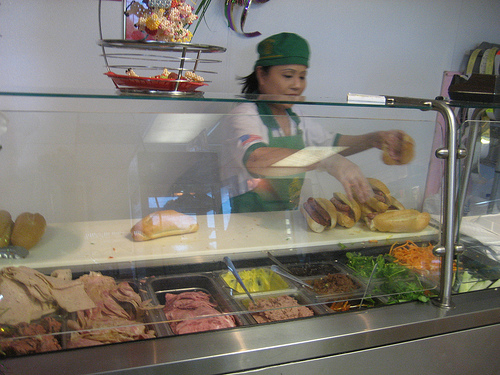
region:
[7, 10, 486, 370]
photograph taken in a sandwich shop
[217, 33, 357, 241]
woman making sandwiches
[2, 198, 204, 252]
white bread rolls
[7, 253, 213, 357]
different meats for sandwiches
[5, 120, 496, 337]
pieces of plastic covering food from customers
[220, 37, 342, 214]
woman wearing a green apron and hat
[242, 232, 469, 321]
garnishes for sandwiches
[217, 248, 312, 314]
silver spoons in the containers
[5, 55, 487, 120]
glass counter top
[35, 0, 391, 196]
walls painted solid white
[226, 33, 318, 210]
woman wearing a green apron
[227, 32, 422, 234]
woman stacking sandwiches on a counter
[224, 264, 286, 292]
container of mustard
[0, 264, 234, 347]
containers of deli meat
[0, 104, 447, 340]
glass partition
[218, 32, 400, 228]
woman wearing an apron and a green hat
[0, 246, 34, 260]
silver tongs sitting on the counter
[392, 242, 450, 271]
container of shredded carrots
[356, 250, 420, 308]
containers of green vegetables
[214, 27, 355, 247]
woman working at a sandwich counter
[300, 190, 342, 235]
sub sandwich on line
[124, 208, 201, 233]
bread of sandwich on creation line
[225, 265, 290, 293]
mayonaise in metal tub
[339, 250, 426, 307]
lettuce in metal tub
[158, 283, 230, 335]
meat in metal tub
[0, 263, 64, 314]
meat in metal tub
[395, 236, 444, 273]
shredded food in metal tub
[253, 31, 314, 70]
green hat on ladys head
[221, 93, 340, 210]
woman wearing green and white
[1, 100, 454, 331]
glass protector for sanitary reasons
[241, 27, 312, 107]
woman wearing green cap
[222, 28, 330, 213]
woman wearing green apron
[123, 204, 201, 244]
loaf of light colored bread on white cutting board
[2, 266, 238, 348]
piles of cold cuts behind glass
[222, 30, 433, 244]
female worker preparing sandwiches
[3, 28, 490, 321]
one woman working behind glass counter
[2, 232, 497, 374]
industrial stainless steel food counter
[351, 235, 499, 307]
vegetables in industrial kitchen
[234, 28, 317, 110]
dark haired Asian woman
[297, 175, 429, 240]
several meat heros on white cutting board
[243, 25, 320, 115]
head of a person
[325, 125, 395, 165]
arm of a person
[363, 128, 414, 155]
hand of a person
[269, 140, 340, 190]
arm of a person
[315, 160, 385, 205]
hand of a person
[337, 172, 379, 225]
fingers of a person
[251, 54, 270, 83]
ear of a person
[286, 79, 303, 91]
nose of a person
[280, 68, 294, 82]
eye of a person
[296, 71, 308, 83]
eye of a person